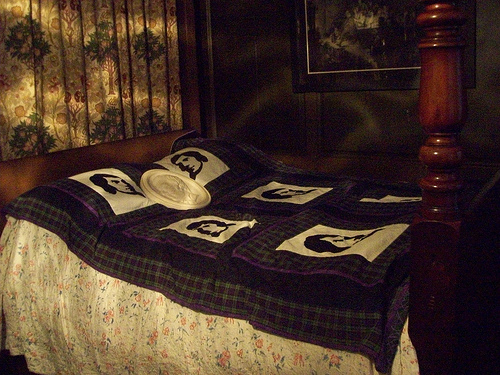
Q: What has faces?
A: Bedspread.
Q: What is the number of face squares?
A: 6.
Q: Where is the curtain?
A: Behind headboard.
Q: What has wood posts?
A: Bed.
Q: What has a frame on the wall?
A: Picture.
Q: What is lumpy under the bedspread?
A: Pillows.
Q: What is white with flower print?
A: Spread on side of bead.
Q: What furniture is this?
A: Bed.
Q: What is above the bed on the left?
A: Curtain.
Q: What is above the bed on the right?
A: Picture.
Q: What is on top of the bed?
A: Blanket.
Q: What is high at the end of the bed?
A: Posts.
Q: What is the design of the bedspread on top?
A: Plaid.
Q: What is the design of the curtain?
A: Trees.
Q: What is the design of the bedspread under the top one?
A: Floral.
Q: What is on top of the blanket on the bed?
A: Pillow.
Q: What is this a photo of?
A: A bed.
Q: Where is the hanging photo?
A: On the wall.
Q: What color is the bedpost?
A: Brown.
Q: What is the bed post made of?
A: Wood.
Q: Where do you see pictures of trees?
A: On the drapes.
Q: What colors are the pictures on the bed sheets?
A: Black and white.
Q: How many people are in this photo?
A: Zero.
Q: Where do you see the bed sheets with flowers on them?
A: On the bed.